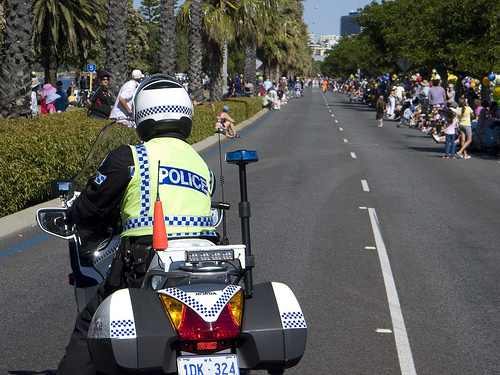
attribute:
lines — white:
[346, 152, 422, 369]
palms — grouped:
[41, 0, 324, 100]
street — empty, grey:
[272, 72, 431, 370]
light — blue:
[222, 150, 268, 168]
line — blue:
[7, 235, 43, 270]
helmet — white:
[129, 66, 196, 137]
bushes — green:
[6, 85, 281, 198]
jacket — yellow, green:
[76, 149, 219, 237]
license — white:
[177, 337, 240, 372]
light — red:
[183, 298, 233, 344]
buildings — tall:
[284, 8, 337, 57]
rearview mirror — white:
[28, 198, 74, 242]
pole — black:
[229, 165, 258, 301]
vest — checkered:
[121, 147, 207, 235]